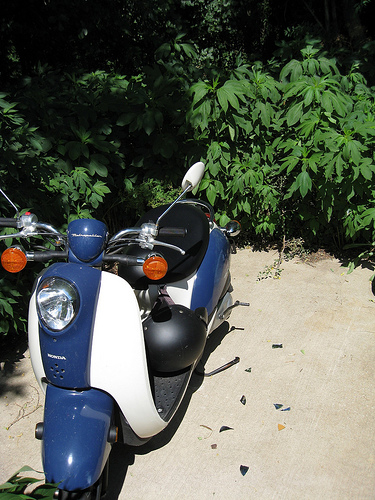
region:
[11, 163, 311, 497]
a motorcycle parked on the cement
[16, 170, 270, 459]
a blue and white motorcyle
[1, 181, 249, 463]
a blue and white bike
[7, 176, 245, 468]
a blue and white bike parked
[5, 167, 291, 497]
a motorcycle standing up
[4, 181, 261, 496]
a blue and white bike standing up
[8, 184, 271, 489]
a blue and white motorcycle standing up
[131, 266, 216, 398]
a helmet on the bike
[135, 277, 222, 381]
a helmet on the black motorcycle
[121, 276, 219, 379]
a black helmet sitting on bike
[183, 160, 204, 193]
Rearview of a motorcycle mirror.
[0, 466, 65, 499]
Green leaves of a plant.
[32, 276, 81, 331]
Headlight to a motorcycle.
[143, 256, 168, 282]
Right turn signal light.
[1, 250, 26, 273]
Left turn signal light.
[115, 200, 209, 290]
Black motorcycle seat.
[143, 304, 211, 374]
Black motorcycle helmet.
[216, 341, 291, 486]
Broken pieces of motorcycle.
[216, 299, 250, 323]
Motorcycle kick stand.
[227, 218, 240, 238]
Back tail light of motorcycle.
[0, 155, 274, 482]
white and blue scooter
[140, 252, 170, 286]
round orange headlight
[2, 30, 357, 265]
leafy bushes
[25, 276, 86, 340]
big round shiny headlight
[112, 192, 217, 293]
black seat on a scooter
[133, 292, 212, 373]
black helmet hanging from a scooter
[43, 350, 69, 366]
white letters at the front of a scooter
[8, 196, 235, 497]
small scooter with a black seat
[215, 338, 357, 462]
light grey pavement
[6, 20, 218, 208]
shadows on the leaves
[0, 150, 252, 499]
a motorscooter parked in dirt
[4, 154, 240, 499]
a blue and white motorscooter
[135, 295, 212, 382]
a black matt colored helmet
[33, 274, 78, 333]
the headlight of the scooter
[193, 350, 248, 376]
the kick stand of the scooter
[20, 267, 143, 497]
the front of the scooter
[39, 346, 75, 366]
brand name of a scooter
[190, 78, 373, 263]
thick foliage behind the scooter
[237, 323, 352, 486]
a concrete slab beneath the scooter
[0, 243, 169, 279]
turn indicators on the scooter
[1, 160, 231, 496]
blue and white motor scooter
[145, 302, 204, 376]
black motorcycle helmet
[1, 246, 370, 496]
sandy parking spot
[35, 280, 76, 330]
motor scooter's headlight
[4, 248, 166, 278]
two orange safety lights on the motor scooter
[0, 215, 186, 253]
motor scooter's handle bars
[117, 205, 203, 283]
black leather scooter seat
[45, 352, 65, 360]
Honda logo on front of scooter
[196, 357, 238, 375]
motor scooter's kickstand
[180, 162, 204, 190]
white rear view mirror